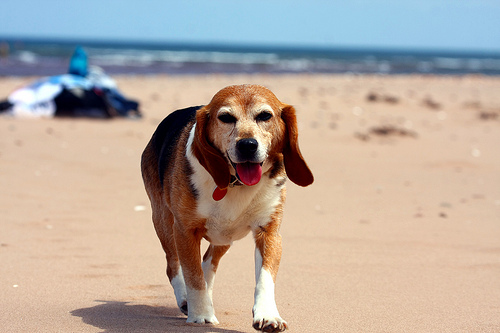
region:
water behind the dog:
[37, 43, 490, 62]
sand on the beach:
[60, 60, 481, 271]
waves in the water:
[107, 51, 269, 69]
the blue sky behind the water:
[4, 10, 497, 36]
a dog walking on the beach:
[123, 99, 340, 330]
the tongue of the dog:
[236, 165, 265, 182]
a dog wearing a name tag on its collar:
[195, 93, 280, 196]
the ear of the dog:
[283, 110, 318, 180]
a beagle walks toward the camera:
[141, 83, 306, 327]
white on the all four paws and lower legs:
[166, 261, 286, 331]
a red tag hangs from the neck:
[210, 181, 229, 201]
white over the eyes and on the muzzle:
[216, 98, 274, 160]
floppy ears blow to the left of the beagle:
[280, 104, 313, 191]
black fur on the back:
[142, 99, 204, 184]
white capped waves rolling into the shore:
[108, 51, 498, 70]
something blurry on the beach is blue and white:
[13, 43, 117, 120]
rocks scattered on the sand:
[362, 78, 498, 143]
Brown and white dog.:
[137, 82, 310, 330]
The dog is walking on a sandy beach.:
[0, 73, 498, 332]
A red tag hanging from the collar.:
[210, 182, 227, 202]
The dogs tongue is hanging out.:
[233, 160, 265, 187]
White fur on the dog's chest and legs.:
[140, 83, 313, 328]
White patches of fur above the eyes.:
[213, 104, 275, 123]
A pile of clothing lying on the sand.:
[0, 46, 142, 114]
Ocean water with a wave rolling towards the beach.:
[0, 35, 496, 75]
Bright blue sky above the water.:
[0, 0, 498, 46]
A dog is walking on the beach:
[50, 41, 427, 329]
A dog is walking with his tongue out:
[50, 32, 421, 328]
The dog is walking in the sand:
[90, 62, 415, 328]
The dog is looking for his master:
[92, 67, 392, 327]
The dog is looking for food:
[110, 45, 375, 327]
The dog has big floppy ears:
[80, 62, 425, 328]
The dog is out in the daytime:
[85, 70, 375, 326]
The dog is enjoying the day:
[126, 47, 396, 330]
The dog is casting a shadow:
[51, 57, 375, 332]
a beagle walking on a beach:
[141, 83, 316, 332]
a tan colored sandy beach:
[2, 71, 493, 331]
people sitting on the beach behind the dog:
[6, 45, 141, 120]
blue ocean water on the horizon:
[2, 36, 499, 69]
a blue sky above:
[0, 0, 497, 50]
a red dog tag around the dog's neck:
[209, 183, 229, 200]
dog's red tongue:
[235, 166, 260, 186]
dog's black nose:
[237, 140, 258, 155]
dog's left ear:
[281, 107, 315, 187]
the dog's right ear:
[193, 108, 225, 185]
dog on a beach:
[109, 54, 344, 327]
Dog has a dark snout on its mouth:
[230, 130, 265, 169]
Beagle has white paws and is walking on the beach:
[151, 236, 346, 328]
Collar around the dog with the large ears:
[164, 150, 320, 269]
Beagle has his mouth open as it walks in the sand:
[201, 126, 305, 203]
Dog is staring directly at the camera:
[176, 73, 362, 251]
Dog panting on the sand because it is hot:
[97, 54, 367, 296]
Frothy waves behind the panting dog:
[26, 28, 492, 106]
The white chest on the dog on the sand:
[187, 153, 305, 286]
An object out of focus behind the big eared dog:
[17, 39, 146, 145]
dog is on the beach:
[90, 63, 313, 330]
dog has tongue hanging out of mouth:
[224, 149, 275, 187]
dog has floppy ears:
[276, 97, 323, 199]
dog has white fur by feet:
[247, 243, 285, 317]